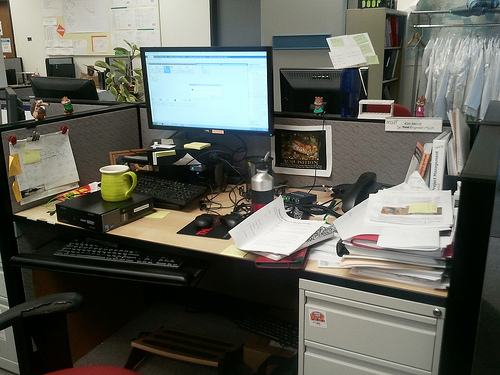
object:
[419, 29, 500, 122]
smocks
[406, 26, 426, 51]
hangers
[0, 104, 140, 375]
cubicle dividers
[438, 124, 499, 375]
cubicle dividers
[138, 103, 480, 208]
cubicle dividers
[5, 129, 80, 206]
white calendar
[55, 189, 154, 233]
cpu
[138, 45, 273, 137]
computer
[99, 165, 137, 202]
mug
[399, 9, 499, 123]
hangers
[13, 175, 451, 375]
desk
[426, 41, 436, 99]
top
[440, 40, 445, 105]
top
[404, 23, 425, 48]
hanger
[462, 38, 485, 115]
top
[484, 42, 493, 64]
top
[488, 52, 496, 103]
top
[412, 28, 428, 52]
hanger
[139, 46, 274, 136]
computer monitor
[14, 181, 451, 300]
table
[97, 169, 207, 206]
keyboard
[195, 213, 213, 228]
mouse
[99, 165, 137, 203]
cup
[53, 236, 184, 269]
keyboard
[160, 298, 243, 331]
floor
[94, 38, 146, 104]
plant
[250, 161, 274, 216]
bottle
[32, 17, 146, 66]
wall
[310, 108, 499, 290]
paperwork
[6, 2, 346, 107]
wall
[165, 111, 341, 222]
wires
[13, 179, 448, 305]
desk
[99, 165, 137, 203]
coffee mug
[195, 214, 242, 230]
mouse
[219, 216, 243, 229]
mouse